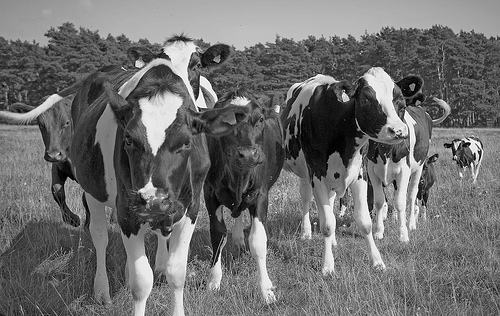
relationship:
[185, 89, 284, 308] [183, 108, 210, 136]
cow has ear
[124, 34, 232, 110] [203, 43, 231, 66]
cow has ear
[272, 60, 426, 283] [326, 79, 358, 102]
cow has ear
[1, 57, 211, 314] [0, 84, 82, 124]
cow has tail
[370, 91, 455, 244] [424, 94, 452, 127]
cow has tail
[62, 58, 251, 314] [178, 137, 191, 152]
cow has eye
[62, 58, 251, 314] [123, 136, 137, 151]
cow has eye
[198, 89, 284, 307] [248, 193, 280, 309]
cow has leg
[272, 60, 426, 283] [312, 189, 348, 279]
cow has leg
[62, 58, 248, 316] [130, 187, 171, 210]
cow has nose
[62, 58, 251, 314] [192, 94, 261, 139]
cow has ear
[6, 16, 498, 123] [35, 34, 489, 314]
trees behind cows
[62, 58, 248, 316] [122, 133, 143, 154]
cow has eye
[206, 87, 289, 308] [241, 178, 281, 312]
cow has leg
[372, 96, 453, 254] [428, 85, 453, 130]
cow has tail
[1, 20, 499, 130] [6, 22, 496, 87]
forest on background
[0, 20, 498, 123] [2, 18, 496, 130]
trees on row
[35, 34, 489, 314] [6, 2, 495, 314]
cows in photo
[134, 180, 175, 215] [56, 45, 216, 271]
nose on cow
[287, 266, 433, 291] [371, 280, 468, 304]
grass on ground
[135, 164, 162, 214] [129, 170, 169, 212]
spot on nose